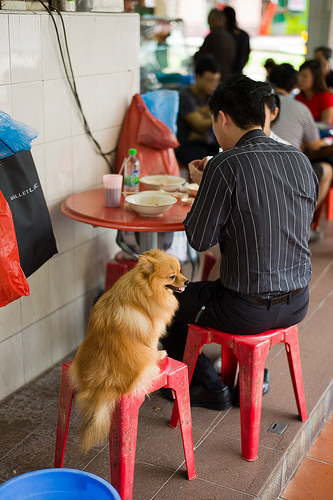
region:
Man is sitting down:
[163, 75, 317, 410]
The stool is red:
[170, 322, 307, 461]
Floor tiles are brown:
[0, 258, 331, 498]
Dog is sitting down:
[69, 249, 188, 452]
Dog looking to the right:
[138, 249, 189, 292]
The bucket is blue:
[1, 467, 119, 498]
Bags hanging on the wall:
[0, 116, 58, 305]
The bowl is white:
[126, 190, 176, 216]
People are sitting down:
[178, 59, 331, 242]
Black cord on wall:
[39, 0, 117, 170]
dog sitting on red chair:
[69, 248, 189, 455]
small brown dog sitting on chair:
[68, 250, 186, 452]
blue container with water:
[0, 466, 123, 498]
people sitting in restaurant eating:
[165, 3, 331, 408]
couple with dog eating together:
[159, 73, 316, 406]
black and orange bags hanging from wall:
[0, 137, 58, 308]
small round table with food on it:
[60, 185, 209, 334]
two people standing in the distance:
[195, 6, 251, 75]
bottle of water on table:
[127, 149, 138, 196]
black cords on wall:
[41, 3, 118, 173]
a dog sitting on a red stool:
[45, 247, 203, 499]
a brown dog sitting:
[68, 248, 189, 450]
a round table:
[59, 171, 205, 237]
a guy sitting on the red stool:
[157, 72, 310, 462]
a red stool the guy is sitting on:
[163, 324, 310, 462]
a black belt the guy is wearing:
[227, 286, 306, 307]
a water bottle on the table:
[122, 147, 141, 198]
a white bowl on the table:
[122, 191, 177, 216]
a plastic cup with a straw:
[101, 156, 126, 209]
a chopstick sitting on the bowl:
[118, 189, 185, 194]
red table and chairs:
[78, 177, 310, 399]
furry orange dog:
[73, 242, 195, 462]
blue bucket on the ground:
[8, 462, 140, 498]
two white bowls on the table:
[133, 168, 176, 218]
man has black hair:
[209, 69, 265, 138]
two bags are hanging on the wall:
[2, 115, 54, 317]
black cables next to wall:
[38, 7, 153, 184]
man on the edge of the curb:
[251, 381, 311, 497]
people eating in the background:
[200, 8, 327, 118]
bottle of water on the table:
[120, 146, 146, 193]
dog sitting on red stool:
[44, 239, 202, 497]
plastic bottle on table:
[74, 128, 202, 242]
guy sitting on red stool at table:
[170, 79, 330, 398]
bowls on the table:
[112, 153, 205, 225]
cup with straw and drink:
[86, 150, 133, 215]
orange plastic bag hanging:
[1, 184, 78, 345]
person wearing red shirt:
[282, 47, 331, 145]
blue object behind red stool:
[3, 353, 130, 499]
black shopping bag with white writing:
[0, 136, 78, 290]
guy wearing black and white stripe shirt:
[163, 69, 317, 333]